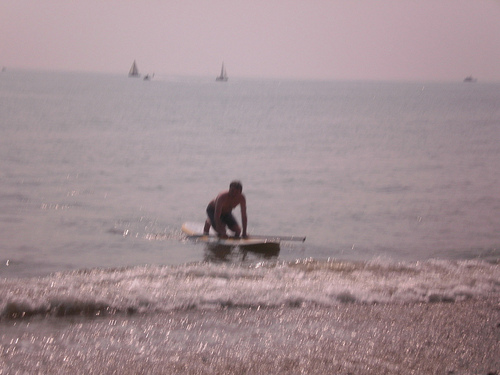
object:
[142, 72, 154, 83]
small boats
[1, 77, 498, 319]
water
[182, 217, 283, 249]
surfboard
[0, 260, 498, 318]
wave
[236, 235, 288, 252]
front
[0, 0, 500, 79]
cloudy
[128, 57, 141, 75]
sail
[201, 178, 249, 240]
man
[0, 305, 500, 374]
shore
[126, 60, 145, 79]
sailboat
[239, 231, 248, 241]
hand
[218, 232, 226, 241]
hand